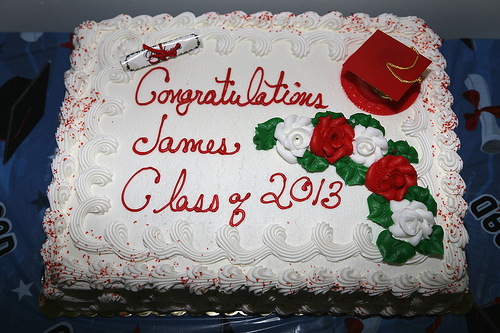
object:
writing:
[132, 66, 331, 116]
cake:
[41, 8, 476, 319]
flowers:
[387, 197, 439, 247]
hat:
[338, 26, 434, 117]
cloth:
[1, 28, 500, 332]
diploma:
[116, 31, 210, 75]